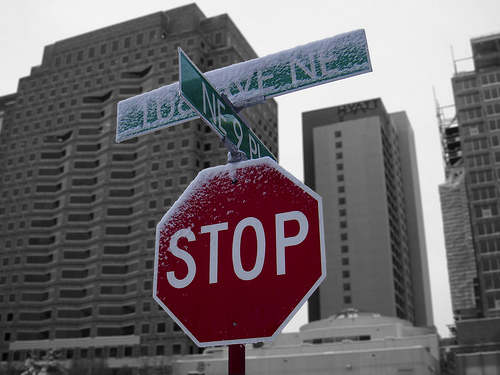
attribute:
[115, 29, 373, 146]
street sign — snowy, green, white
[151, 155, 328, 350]
stop sign — red, white, snowy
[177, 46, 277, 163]
street sign — green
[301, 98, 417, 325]
building — tall, gray, cement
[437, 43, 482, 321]
repair — reconstruction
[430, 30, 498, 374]
building — gray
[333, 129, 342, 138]
window — square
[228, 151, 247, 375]
pole — red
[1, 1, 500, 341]
sky — pale blue, pale, cloudy, gray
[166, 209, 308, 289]
word — white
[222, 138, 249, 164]
screw — metal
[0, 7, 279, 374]
building — wide, tall